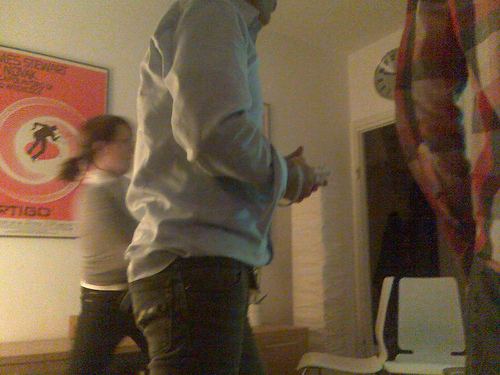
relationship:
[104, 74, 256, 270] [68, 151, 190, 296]
man wearing shirt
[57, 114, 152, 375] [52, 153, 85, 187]
girl wearing a ponytail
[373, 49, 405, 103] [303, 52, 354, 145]
clock hanging on wall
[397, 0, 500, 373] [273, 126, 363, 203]
man watching a game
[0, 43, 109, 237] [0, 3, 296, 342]
picture hanging on wall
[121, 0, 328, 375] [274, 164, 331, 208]
man holding game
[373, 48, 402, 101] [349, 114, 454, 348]
clock hanging above doorway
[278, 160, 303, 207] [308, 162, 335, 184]
strap of controller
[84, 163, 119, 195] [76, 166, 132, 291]
collar of shirt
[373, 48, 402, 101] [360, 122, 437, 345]
clock over door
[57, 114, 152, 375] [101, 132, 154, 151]
girl wearing glasses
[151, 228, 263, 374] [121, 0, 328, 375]
jeans on man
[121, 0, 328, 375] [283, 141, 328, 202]
man has hand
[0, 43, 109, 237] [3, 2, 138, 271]
picture hanging on wall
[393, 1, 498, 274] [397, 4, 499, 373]
shirt on man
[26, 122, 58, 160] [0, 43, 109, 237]
silhouette on picture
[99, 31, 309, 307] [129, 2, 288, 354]
shirt on man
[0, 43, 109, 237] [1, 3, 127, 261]
picture on wall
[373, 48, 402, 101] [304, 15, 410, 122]
clock on wall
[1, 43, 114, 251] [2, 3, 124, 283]
artwork on wall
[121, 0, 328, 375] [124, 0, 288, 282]
man wearing shirt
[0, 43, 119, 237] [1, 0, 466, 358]
picture on wall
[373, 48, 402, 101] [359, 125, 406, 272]
clock over door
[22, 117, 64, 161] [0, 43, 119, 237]
man in picture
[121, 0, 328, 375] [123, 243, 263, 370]
man wearing jeans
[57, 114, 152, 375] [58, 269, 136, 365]
girl wearing jeans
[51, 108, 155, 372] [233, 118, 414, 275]
girl playing video games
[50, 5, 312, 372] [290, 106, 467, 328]
couple playing a game